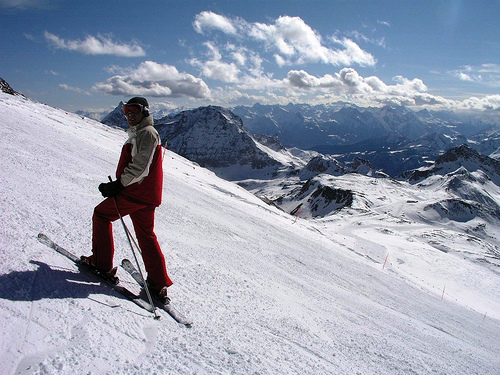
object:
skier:
[80, 96, 171, 296]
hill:
[0, 76, 499, 374]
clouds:
[457, 68, 500, 111]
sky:
[0, 0, 499, 122]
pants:
[92, 193, 172, 289]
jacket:
[116, 116, 163, 206]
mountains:
[100, 101, 499, 175]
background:
[0, 0, 500, 316]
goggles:
[122, 103, 149, 115]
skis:
[120, 258, 194, 325]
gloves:
[98, 179, 125, 197]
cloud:
[95, 59, 212, 101]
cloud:
[192, 10, 375, 69]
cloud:
[239, 68, 426, 97]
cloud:
[43, 27, 147, 59]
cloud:
[373, 93, 445, 109]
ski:
[37, 233, 156, 312]